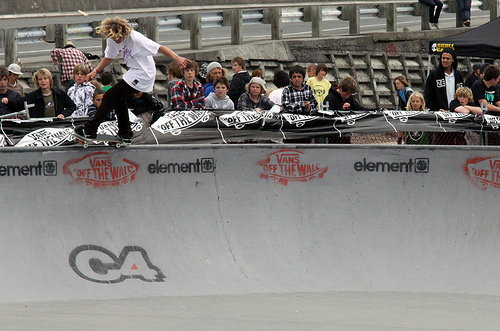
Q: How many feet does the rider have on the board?
A: 2.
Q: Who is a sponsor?
A: Van's.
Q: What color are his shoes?
A: Black.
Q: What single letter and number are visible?
A: C4.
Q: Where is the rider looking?
A: Down.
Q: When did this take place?
A: Daytime.